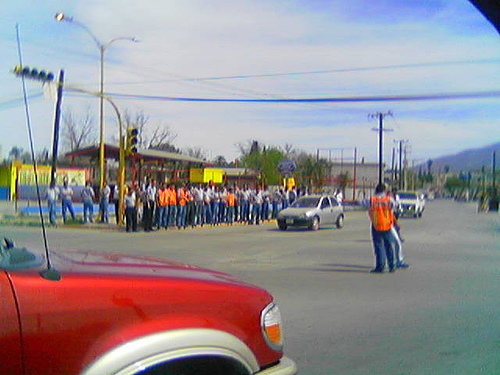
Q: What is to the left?
A: Hood of a red truck.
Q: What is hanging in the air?
A: A traffic signal.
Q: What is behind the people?
A: A street light.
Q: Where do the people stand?
A: On pavement.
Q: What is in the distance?
A: Mountains.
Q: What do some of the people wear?
A: Orange vests.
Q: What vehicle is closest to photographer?
A: A red SUV driving on street.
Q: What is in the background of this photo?
A: Trees with no leaves.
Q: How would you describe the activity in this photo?
A: There are people standing along the street.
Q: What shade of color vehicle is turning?
A: A red vehicle.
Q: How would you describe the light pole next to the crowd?
A: A double headed light pole.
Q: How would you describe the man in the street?
A: A guy in an orange vest.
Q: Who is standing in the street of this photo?
A: A guy in an orange vest.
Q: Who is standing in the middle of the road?
A: A guy in an orange vest.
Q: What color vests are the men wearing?
A: Orange.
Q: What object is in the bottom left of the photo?
A: Car.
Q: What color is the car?
A: Red.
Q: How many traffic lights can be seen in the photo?
A: One.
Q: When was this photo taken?
A: Daytime.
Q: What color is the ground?
A: Grey.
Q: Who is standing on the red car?
A: No one.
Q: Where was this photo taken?
A: On a street.